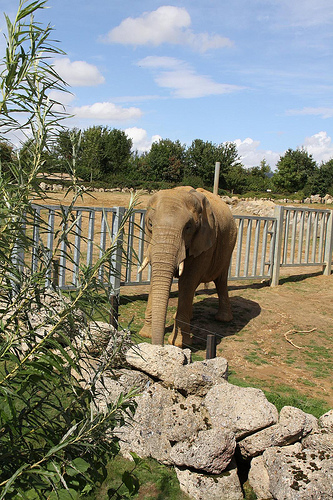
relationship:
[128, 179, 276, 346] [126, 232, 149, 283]
elephant has left tusk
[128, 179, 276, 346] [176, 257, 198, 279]
elephant has right tusk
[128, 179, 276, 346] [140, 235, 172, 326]
elephant has trunk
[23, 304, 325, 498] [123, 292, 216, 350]
wall behind fence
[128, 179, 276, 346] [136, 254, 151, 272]
elephant has right tusk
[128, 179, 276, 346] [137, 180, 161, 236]
elephant has ear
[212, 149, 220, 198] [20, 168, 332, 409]
post inside enclosure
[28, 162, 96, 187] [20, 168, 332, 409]
house inside enclosure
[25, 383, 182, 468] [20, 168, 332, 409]
grass inside enclosure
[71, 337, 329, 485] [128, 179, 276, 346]
rocks near elephant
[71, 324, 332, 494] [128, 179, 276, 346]
boulders near elephant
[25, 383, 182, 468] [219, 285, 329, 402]
grass on ground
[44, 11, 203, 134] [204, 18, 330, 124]
clouds floating in sky